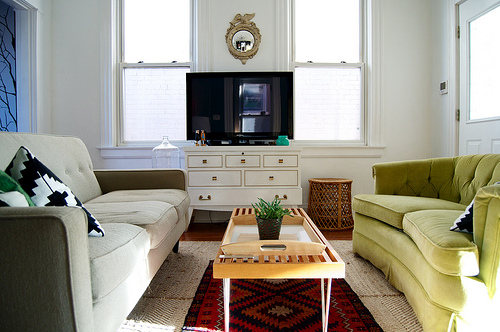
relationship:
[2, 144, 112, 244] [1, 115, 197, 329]
pillows on a sofa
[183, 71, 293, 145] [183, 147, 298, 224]
television on dresser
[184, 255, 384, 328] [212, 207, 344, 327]
rug under table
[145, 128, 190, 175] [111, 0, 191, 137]
glass jug in front of window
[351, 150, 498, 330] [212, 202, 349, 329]
green sofa to right of coffee table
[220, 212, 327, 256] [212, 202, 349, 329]
tray on top of coffee table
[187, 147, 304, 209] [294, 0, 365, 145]
dresser beside window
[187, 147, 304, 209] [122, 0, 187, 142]
dresser beside window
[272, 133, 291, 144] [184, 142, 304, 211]
jar on dresser